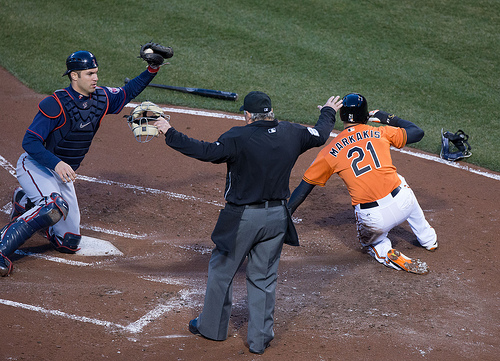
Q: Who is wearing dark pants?
A: The umpire.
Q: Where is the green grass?
A: In the field.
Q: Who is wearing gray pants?
A: The umpire.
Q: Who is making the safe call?
A: Umpire.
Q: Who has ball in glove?
A: Catcher.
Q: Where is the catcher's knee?
A: On home plate.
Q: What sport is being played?
A: Baseball.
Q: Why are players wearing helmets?
A: To protect their heads.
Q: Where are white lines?
A: On the dirt.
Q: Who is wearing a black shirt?
A: Umpire.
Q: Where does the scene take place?
A: At a baseball game.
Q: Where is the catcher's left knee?
A: On home plate.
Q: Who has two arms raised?
A: The umpire.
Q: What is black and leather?
A: Baseball glove.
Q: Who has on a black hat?
A: Umpire.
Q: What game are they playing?
A: Baseball.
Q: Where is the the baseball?
A: In the catcher's mitt.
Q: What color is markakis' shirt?
A: Orange.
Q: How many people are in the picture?
A: 3.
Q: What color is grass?
A: Green.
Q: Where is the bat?
A: In the grass.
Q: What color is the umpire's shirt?
A: Black.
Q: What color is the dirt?
A: Brown.